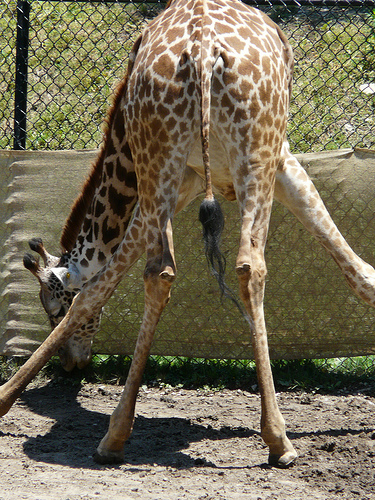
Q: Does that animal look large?
A: Yes, the animal is large.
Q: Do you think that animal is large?
A: Yes, the animal is large.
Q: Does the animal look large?
A: Yes, the animal is large.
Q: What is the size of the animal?
A: The animal is large.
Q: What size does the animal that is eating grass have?
A: The animal has large size.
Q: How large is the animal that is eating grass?
A: The animal is large.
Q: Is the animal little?
A: No, the animal is large.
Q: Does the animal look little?
A: No, the animal is large.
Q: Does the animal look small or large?
A: The animal is large.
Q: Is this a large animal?
A: Yes, this is a large animal.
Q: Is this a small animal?
A: No, this is a large animal.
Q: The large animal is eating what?
A: The animal is eating grass.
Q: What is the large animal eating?
A: The animal is eating grass.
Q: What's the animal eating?
A: The animal is eating grass.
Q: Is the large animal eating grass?
A: Yes, the animal is eating grass.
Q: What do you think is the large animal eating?
A: The animal is eating grass.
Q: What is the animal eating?
A: The animal is eating grass.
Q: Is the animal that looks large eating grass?
A: Yes, the animal is eating grass.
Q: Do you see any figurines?
A: No, there are no figurines.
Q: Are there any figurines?
A: No, there are no figurines.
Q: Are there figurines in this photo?
A: No, there are no figurines.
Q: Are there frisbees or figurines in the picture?
A: No, there are no figurines or frisbees.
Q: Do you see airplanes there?
A: No, there are no airplanes.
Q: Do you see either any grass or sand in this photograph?
A: Yes, there is grass.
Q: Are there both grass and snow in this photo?
A: No, there is grass but no snow.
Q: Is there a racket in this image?
A: No, there are no rackets.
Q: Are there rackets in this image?
A: No, there are no rackets.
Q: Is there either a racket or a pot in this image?
A: No, there are no rackets or pots.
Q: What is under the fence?
A: The grass is under the fence.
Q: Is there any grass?
A: Yes, there is grass.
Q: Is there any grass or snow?
A: Yes, there is grass.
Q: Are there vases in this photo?
A: No, there are no vases.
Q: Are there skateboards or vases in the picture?
A: No, there are no vases or skateboards.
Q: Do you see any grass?
A: Yes, there is grass.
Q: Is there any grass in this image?
A: Yes, there is grass.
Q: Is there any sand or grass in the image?
A: Yes, there is grass.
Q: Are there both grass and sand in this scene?
A: Yes, there are both grass and sand.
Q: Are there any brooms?
A: No, there are no brooms.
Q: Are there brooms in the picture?
A: No, there are no brooms.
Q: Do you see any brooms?
A: No, there are no brooms.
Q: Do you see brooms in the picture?
A: No, there are no brooms.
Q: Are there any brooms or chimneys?
A: No, there are no brooms or chimneys.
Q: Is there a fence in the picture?
A: Yes, there is a fence.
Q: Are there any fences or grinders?
A: Yes, there is a fence.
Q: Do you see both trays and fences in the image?
A: No, there is a fence but no trays.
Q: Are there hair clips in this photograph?
A: No, there are no hair clips.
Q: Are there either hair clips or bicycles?
A: No, there are no hair clips or bicycles.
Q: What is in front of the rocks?
A: The fence is in front of the rocks.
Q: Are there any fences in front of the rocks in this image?
A: Yes, there is a fence in front of the rocks.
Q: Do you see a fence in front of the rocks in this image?
A: Yes, there is a fence in front of the rocks.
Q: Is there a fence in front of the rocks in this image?
A: Yes, there is a fence in front of the rocks.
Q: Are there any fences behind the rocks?
A: No, the fence is in front of the rocks.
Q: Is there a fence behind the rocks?
A: No, the fence is in front of the rocks.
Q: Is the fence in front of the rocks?
A: Yes, the fence is in front of the rocks.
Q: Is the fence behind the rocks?
A: No, the fence is in front of the rocks.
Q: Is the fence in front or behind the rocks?
A: The fence is in front of the rocks.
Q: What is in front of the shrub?
A: The fence is in front of the shrub.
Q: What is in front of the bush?
A: The fence is in front of the shrub.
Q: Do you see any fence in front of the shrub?
A: Yes, there is a fence in front of the shrub.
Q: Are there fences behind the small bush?
A: No, the fence is in front of the bush.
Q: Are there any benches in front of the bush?
A: No, there is a fence in front of the bush.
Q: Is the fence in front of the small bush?
A: Yes, the fence is in front of the shrub.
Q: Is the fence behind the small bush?
A: No, the fence is in front of the shrub.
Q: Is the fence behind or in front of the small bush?
A: The fence is in front of the bush.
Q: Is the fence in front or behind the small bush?
A: The fence is in front of the bush.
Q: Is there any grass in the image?
A: Yes, there is grass.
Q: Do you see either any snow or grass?
A: Yes, there is grass.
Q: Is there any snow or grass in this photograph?
A: Yes, there is grass.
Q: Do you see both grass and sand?
A: Yes, there are both grass and sand.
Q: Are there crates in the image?
A: No, there are no crates.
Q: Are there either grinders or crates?
A: No, there are no crates or grinders.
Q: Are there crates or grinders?
A: No, there are no crates or grinders.